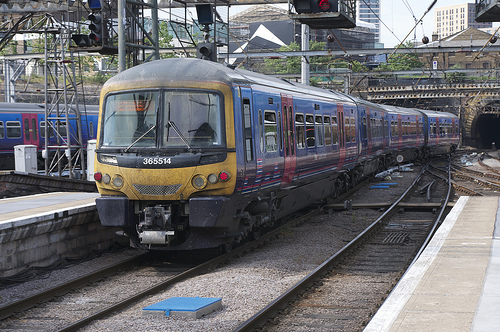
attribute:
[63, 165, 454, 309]
tracks — next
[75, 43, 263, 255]
front — yellow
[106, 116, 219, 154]
wipers — windshield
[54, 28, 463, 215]
cars — three passenger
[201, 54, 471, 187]
sides — blue and red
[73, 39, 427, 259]
train — blue with red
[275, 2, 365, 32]
signal — traffic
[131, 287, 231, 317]
object — blue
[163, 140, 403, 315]
lines — small thin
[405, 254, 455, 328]
edge — white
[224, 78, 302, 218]
door — red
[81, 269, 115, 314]
spot — small white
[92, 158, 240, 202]
light — red circular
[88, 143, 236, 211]
light — red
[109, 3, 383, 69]
building — square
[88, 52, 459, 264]
train — dirty yellow front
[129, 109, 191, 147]
wipers — windshield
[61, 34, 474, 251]
train — face yellow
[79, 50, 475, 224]
car — train, blue and red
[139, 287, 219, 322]
box — BLUE